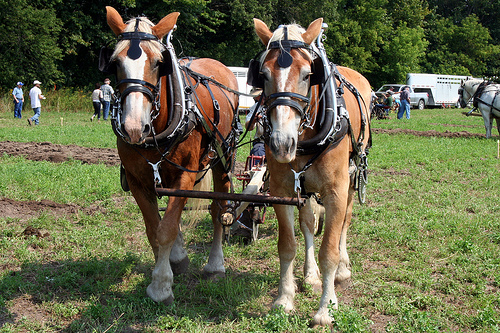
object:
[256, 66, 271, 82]
eye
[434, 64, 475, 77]
bush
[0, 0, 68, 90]
bush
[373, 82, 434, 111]
truck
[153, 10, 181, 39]
ear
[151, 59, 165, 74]
eye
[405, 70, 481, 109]
horse trailer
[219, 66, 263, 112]
horse trailer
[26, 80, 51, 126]
man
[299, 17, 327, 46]
ear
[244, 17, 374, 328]
horse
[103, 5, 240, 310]
horse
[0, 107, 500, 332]
field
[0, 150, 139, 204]
grass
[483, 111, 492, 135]
leg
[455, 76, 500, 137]
horse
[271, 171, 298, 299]
leg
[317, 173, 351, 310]
horse leg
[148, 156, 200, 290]
horse leg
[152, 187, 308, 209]
pole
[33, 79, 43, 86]
caps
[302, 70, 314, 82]
eye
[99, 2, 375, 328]
cart